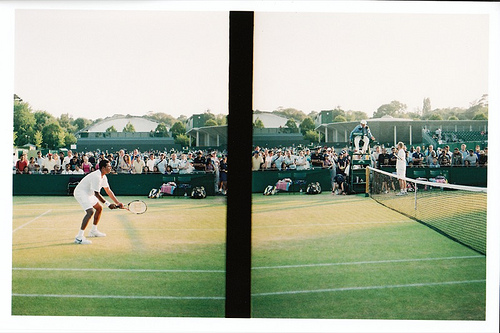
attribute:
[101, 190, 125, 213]
sweatband — white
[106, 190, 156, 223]
racquet — tennis racquet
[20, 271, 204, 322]
lines — white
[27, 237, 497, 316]
floor — court floor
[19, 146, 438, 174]
spectators — watching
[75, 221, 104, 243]
shoes — white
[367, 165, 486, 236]
net — tennis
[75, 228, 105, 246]
shoes — white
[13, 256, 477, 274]
line — white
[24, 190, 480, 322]
court floor — green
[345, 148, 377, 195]
referee stand — green